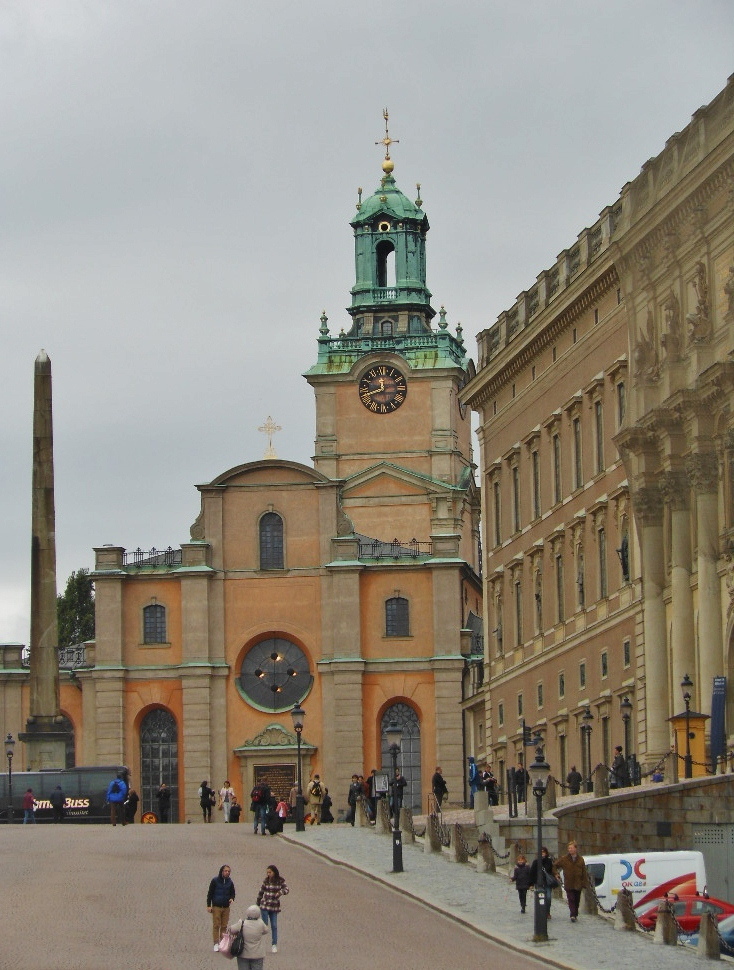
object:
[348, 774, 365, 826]
person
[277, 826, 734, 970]
sidewalk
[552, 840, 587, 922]
person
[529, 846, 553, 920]
person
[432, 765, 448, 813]
person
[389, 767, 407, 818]
person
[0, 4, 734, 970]
outdoors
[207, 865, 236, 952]
person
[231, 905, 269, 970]
person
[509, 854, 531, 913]
person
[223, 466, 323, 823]
wall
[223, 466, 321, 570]
wall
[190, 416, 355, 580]
building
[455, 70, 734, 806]
building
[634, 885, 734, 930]
car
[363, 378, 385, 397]
hands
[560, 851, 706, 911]
van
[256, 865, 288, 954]
person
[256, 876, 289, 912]
plaid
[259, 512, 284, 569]
window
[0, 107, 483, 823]
building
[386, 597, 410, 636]
window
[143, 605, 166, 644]
window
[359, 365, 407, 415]
clock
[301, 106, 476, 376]
top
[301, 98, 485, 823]
tower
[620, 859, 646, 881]
logo